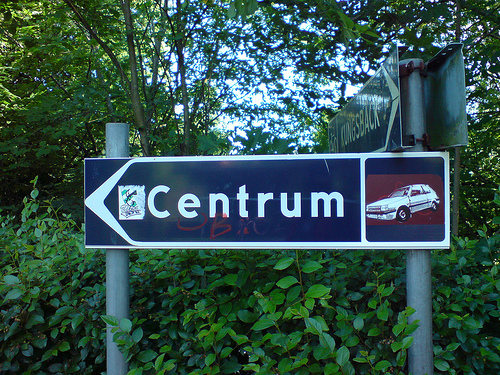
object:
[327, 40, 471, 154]
sign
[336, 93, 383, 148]
kingback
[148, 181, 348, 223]
centram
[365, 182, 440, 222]
car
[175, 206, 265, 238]
graffiti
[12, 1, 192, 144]
trees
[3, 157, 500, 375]
bushes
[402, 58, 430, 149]
bolts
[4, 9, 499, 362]
picture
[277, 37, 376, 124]
sun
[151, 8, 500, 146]
sky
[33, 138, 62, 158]
leaves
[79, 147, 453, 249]
road sign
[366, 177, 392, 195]
red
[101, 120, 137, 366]
post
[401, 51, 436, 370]
post